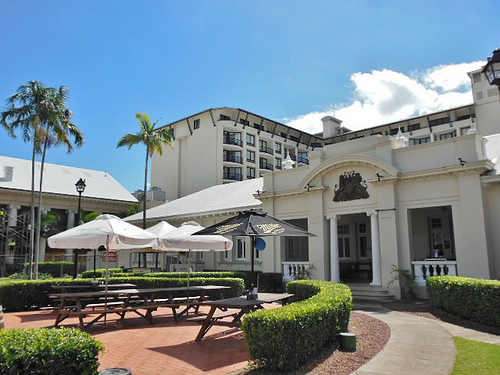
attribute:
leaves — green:
[240, 278, 352, 372]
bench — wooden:
[58, 304, 178, 326]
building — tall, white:
[120, 70, 499, 303]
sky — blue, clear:
[1, 0, 497, 196]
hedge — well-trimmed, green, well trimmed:
[242, 278, 352, 373]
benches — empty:
[52, 280, 211, 323]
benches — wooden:
[47, 282, 208, 316]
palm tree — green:
[2, 79, 83, 280]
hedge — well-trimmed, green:
[426, 274, 499, 332]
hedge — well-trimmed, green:
[0, 330, 99, 371]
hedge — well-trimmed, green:
[0, 284, 101, 303]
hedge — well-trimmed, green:
[99, 275, 244, 299]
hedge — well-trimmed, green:
[17, 260, 78, 279]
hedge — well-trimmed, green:
[104, 272, 237, 281]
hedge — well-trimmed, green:
[82, 267, 130, 281]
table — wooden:
[199, 288, 292, 348]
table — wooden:
[51, 283, 183, 328]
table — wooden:
[153, 277, 230, 320]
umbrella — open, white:
[46, 209, 149, 292]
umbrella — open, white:
[138, 215, 176, 300]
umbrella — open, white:
[157, 216, 230, 288]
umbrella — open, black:
[194, 207, 320, 294]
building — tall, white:
[143, 52, 499, 304]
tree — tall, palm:
[121, 113, 177, 283]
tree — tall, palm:
[15, 76, 38, 280]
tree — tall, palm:
[33, 84, 83, 284]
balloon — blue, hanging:
[253, 237, 267, 250]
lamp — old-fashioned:
[74, 179, 84, 194]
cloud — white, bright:
[269, 60, 499, 139]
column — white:
[366, 210, 381, 284]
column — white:
[326, 216, 341, 286]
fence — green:
[241, 260, 359, 366]